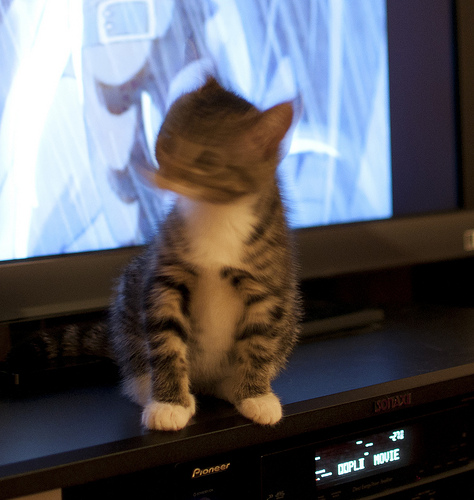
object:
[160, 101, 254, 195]
face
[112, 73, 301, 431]
kitten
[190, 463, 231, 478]
brand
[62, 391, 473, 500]
vcr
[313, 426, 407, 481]
lights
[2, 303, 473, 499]
table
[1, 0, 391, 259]
movie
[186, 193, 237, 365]
belly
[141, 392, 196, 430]
paw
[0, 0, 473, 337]
television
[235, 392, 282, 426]
paw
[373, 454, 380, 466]
letter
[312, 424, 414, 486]
display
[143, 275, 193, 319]
stripes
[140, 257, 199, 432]
leg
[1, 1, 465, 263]
tv screen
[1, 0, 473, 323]
encasing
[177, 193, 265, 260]
patch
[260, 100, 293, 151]
ear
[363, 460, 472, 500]
shelf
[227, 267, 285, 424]
leg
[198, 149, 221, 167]
eye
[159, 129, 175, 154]
eye